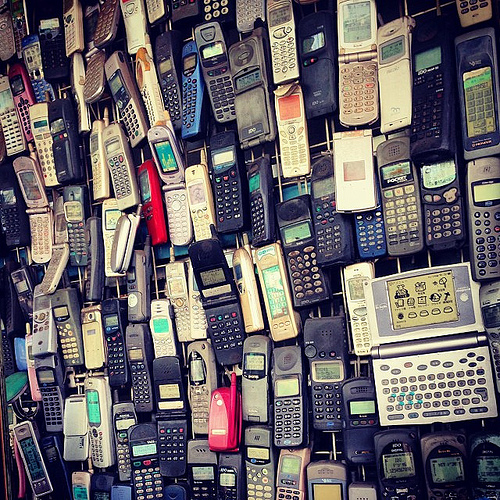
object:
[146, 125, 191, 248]
phone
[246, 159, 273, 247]
cellphone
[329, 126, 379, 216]
cellphone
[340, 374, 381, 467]
cellphone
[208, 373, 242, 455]
cellphone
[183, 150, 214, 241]
cellphone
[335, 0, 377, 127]
cellphone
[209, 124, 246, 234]
cell phone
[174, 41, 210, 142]
handset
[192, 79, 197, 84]
button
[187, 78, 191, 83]
button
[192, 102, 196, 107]
button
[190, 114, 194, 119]
button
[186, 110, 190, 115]
button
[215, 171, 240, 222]
buttons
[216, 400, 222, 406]
white button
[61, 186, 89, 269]
cell phone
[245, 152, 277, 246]
cell phone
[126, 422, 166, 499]
cell phone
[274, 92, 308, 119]
screen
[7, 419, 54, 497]
cell phone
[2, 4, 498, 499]
wall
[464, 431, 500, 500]
phones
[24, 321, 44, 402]
cellphone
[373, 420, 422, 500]
cell phone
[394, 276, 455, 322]
black icons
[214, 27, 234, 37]
wire hook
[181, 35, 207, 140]
cell phone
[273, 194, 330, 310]
cell phone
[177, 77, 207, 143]
phone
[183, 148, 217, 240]
cell phone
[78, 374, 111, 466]
phone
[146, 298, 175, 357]
phone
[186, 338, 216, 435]
phone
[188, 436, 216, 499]
phone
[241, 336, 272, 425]
phone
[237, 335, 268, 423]
phone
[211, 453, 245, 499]
phone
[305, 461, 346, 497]
phone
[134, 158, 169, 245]
phone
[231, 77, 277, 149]
phone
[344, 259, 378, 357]
phone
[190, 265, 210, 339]
phone